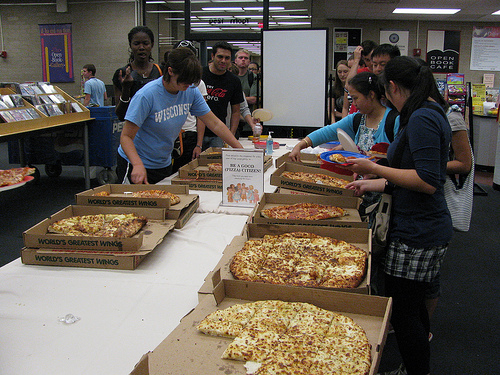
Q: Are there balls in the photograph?
A: No, there are no balls.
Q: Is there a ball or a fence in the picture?
A: No, there are no balls or fences.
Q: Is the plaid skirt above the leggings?
A: Yes, the skirt is above the leggings.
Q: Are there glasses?
A: No, there are no glasses.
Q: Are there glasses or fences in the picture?
A: No, there are no glasses or fences.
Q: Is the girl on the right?
A: Yes, the girl is on the right of the image.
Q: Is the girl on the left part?
A: No, the girl is on the right of the image.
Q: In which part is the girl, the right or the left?
A: The girl is on the right of the image.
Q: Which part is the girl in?
A: The girl is on the right of the image.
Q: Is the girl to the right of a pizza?
A: Yes, the girl is to the right of a pizza.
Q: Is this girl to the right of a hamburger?
A: No, the girl is to the right of a pizza.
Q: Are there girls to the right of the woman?
A: Yes, there is a girl to the right of the woman.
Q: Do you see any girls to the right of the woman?
A: Yes, there is a girl to the right of the woman.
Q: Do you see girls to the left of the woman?
A: No, the girl is to the right of the woman.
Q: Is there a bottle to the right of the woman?
A: No, there is a girl to the right of the woman.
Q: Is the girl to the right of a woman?
A: Yes, the girl is to the right of a woman.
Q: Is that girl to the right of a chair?
A: No, the girl is to the right of a woman.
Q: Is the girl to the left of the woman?
A: No, the girl is to the right of the woman.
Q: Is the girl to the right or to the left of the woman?
A: The girl is to the right of the woman.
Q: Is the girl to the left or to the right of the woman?
A: The girl is to the right of the woman.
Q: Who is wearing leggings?
A: The girl is wearing leggings.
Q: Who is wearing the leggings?
A: The girl is wearing leggings.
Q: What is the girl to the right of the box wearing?
A: The girl is wearing leggings.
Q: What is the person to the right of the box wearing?
A: The girl is wearing leggings.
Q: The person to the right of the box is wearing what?
A: The girl is wearing leggings.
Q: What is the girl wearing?
A: The girl is wearing leggings.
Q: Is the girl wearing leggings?
A: Yes, the girl is wearing leggings.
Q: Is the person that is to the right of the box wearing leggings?
A: Yes, the girl is wearing leggings.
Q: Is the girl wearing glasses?
A: No, the girl is wearing leggings.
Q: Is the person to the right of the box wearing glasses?
A: No, the girl is wearing leggings.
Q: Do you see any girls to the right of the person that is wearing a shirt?
A: Yes, there is a girl to the right of the person.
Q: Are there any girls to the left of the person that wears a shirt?
A: No, the girl is to the right of the person.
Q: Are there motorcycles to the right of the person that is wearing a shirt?
A: No, there is a girl to the right of the person.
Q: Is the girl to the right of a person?
A: Yes, the girl is to the right of a person.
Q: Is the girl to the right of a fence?
A: No, the girl is to the right of a person.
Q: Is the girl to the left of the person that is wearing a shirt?
A: No, the girl is to the right of the person.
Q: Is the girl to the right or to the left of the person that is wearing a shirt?
A: The girl is to the right of the person.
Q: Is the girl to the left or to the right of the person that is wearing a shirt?
A: The girl is to the right of the person.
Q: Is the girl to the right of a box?
A: Yes, the girl is to the right of a box.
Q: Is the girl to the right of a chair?
A: No, the girl is to the right of a box.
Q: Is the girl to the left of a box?
A: No, the girl is to the right of a box.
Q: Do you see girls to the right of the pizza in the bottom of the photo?
A: Yes, there is a girl to the right of the pizza.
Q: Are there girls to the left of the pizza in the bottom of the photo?
A: No, the girl is to the right of the pizza.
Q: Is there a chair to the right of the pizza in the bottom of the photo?
A: No, there is a girl to the right of the pizza.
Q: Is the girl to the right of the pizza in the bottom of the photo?
A: Yes, the girl is to the right of the pizza.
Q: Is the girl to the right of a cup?
A: No, the girl is to the right of the pizza.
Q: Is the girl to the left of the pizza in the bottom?
A: No, the girl is to the right of the pizza.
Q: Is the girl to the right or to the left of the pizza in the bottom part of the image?
A: The girl is to the right of the pizza.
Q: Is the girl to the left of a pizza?
A: No, the girl is to the right of a pizza.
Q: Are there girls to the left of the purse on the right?
A: Yes, there is a girl to the left of the purse.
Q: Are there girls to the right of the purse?
A: No, the girl is to the left of the purse.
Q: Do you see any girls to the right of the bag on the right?
A: No, the girl is to the left of the purse.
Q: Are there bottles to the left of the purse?
A: No, there is a girl to the left of the purse.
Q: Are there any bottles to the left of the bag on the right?
A: No, there is a girl to the left of the purse.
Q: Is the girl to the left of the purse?
A: Yes, the girl is to the left of the purse.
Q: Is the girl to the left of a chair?
A: No, the girl is to the left of the purse.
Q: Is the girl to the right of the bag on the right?
A: No, the girl is to the left of the purse.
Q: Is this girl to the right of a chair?
A: No, the girl is to the right of a box.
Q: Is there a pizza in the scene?
A: Yes, there is a pizza.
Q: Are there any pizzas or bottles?
A: Yes, there is a pizza.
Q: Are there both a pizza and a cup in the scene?
A: No, there is a pizza but no cups.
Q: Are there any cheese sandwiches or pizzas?
A: Yes, there is a cheese pizza.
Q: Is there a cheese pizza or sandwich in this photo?
A: Yes, there is a cheese pizza.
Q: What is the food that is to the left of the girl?
A: The food is a pizza.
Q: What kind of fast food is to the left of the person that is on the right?
A: The food is a pizza.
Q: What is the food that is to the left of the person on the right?
A: The food is a pizza.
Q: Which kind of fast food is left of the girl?
A: The food is a pizza.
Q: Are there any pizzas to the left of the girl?
A: Yes, there is a pizza to the left of the girl.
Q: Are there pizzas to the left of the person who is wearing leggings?
A: Yes, there is a pizza to the left of the girl.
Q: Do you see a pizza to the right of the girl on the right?
A: No, the pizza is to the left of the girl.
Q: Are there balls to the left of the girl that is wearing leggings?
A: No, there is a pizza to the left of the girl.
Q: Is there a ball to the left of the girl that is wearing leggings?
A: No, there is a pizza to the left of the girl.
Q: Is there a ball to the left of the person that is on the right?
A: No, there is a pizza to the left of the girl.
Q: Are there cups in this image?
A: No, there are no cups.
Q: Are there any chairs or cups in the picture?
A: No, there are no cups or chairs.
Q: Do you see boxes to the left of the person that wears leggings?
A: Yes, there is a box to the left of the girl.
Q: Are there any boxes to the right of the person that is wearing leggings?
A: No, the box is to the left of the girl.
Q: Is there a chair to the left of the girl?
A: No, there is a box to the left of the girl.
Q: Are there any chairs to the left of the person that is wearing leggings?
A: No, there is a box to the left of the girl.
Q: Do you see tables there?
A: Yes, there is a table.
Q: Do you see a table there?
A: Yes, there is a table.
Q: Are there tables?
A: Yes, there is a table.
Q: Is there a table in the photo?
A: Yes, there is a table.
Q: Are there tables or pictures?
A: Yes, there is a table.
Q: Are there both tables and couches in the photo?
A: No, there is a table but no couches.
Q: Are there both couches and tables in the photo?
A: No, there is a table but no couches.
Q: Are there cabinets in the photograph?
A: No, there are no cabinets.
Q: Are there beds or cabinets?
A: No, there are no cabinets or beds.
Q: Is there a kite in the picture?
A: No, there are no kites.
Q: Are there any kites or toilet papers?
A: No, there are no kites or toilet papers.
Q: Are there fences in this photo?
A: No, there are no fences.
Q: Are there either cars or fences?
A: No, there are no fences or cars.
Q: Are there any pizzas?
A: Yes, there is a pizza.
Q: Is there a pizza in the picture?
A: Yes, there is a pizza.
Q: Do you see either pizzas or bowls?
A: Yes, there is a pizza.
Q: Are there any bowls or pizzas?
A: Yes, there is a pizza.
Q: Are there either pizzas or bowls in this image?
A: Yes, there is a pizza.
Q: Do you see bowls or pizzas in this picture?
A: Yes, there is a pizza.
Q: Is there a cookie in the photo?
A: No, there are no cookies.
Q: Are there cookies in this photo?
A: No, there are no cookies.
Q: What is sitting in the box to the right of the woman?
A: The pizza is sitting in the box.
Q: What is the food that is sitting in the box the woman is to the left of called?
A: The food is a pizza.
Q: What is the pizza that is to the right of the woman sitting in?
A: The pizza is sitting in the box.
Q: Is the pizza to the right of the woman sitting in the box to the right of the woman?
A: Yes, the pizza is sitting in the box.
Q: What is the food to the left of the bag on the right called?
A: The food is a pizza.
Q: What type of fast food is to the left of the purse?
A: The food is a pizza.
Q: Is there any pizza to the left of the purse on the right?
A: Yes, there is a pizza to the left of the purse.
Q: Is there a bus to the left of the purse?
A: No, there is a pizza to the left of the purse.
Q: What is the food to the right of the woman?
A: The food is a pizza.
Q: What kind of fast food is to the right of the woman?
A: The food is a pizza.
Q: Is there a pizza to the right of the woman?
A: Yes, there is a pizza to the right of the woman.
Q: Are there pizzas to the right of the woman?
A: Yes, there is a pizza to the right of the woman.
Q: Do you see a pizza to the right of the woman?
A: Yes, there is a pizza to the right of the woman.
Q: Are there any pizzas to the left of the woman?
A: No, the pizza is to the right of the woman.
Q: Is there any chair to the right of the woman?
A: No, there is a pizza to the right of the woman.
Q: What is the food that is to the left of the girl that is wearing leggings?
A: The food is a pizza.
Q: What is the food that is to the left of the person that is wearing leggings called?
A: The food is a pizza.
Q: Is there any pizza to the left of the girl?
A: Yes, there is a pizza to the left of the girl.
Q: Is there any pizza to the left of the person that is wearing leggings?
A: Yes, there is a pizza to the left of the girl.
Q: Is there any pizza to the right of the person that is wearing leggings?
A: No, the pizza is to the left of the girl.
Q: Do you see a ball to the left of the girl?
A: No, there is a pizza to the left of the girl.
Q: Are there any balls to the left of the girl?
A: No, there is a pizza to the left of the girl.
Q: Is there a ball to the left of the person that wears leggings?
A: No, there is a pizza to the left of the girl.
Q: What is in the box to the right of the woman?
A: The pizza is in the box.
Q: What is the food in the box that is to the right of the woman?
A: The food is a pizza.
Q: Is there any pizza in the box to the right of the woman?
A: Yes, there is a pizza in the box.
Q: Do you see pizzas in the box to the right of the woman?
A: Yes, there is a pizza in the box.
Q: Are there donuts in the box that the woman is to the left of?
A: No, there is a pizza in the box.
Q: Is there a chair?
A: No, there are no chairs.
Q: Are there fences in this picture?
A: No, there are no fences.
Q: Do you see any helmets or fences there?
A: No, there are no fences or helmets.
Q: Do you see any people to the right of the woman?
A: Yes, there is a person to the right of the woman.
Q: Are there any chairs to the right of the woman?
A: No, there is a person to the right of the woman.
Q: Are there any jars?
A: No, there are no jars.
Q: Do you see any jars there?
A: No, there are no jars.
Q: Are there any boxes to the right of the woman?
A: Yes, there is a box to the right of the woman.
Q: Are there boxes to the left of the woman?
A: No, the box is to the right of the woman.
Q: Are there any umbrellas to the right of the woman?
A: No, there is a box to the right of the woman.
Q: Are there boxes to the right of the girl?
A: No, the box is to the left of the girl.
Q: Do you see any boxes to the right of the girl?
A: No, the box is to the left of the girl.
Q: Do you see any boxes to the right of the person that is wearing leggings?
A: No, the box is to the left of the girl.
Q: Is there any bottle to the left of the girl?
A: No, there is a box to the left of the girl.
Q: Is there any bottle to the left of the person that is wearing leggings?
A: No, there is a box to the left of the girl.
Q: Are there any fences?
A: No, there are no fences.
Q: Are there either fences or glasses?
A: No, there are no fences or glasses.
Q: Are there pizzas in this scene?
A: Yes, there is a pizza.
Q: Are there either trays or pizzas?
A: Yes, there is a pizza.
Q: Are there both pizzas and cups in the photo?
A: No, there is a pizza but no cups.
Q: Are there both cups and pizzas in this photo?
A: No, there is a pizza but no cups.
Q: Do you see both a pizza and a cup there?
A: No, there is a pizza but no cups.